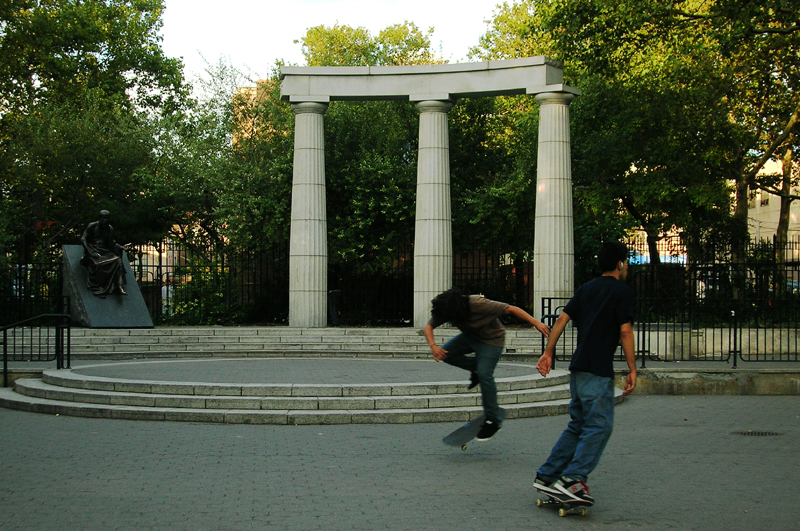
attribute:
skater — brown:
[423, 288, 553, 445]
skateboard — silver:
[443, 408, 511, 453]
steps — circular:
[10, 357, 622, 407]